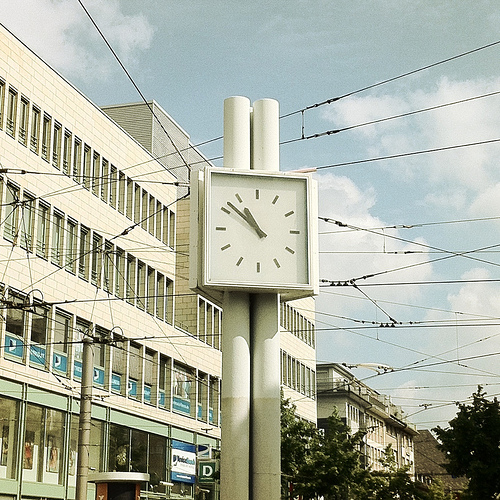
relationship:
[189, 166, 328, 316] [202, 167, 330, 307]
clock on pole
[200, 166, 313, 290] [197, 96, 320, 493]
clock on pole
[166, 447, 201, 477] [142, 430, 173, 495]
sign on window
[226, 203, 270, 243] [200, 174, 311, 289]
hands on clock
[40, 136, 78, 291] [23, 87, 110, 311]
blinds in windows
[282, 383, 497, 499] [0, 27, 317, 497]
trees right of building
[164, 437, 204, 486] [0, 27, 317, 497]
sign on building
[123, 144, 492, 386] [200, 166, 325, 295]
lines running behind clock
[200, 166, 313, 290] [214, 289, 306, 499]
clock attached to pole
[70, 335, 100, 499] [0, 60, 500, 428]
utility pole attached to lines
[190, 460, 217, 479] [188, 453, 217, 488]
d on sign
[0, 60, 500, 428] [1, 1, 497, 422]
lines against sky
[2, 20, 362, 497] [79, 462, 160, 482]
building has awning